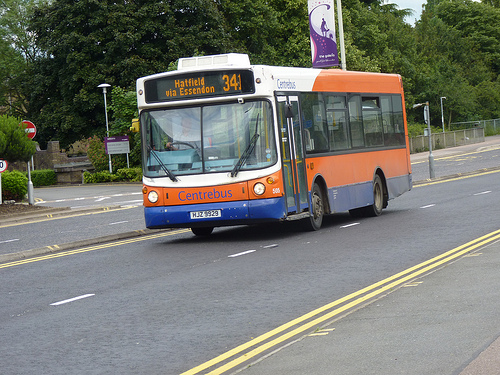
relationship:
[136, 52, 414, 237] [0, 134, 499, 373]
bus on road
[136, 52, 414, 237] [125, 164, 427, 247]
bus has a bottom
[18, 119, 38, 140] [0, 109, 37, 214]
sign behind tree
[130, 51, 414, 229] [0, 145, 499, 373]
bus driving on driveway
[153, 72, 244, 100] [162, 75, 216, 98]
marquee displaying destination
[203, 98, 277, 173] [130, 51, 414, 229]
front window built into bus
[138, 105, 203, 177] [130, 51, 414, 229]
front window built into bus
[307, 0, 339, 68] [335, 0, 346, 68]
banner hanging from pole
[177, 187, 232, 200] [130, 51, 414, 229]
name on bus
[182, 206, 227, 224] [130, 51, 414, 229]
license plate on bus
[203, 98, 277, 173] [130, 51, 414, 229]
front window in front of bus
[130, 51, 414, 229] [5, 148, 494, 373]
bus driving down street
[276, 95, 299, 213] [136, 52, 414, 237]
doors on bus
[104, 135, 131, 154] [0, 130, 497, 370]
sign on street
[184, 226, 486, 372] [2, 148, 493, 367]
curb dividing road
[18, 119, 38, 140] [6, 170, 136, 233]
sign in a driveway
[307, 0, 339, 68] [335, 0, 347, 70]
banner on pole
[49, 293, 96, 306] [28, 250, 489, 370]
median on road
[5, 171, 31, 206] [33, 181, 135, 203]
bush in driveway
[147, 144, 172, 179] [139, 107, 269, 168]
wiper on windshield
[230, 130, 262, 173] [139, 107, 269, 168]
wiper on windshield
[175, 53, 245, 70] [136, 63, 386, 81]
air conditioner on roof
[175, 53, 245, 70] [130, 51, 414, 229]
air conditioner on bus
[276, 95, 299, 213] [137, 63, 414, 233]
doors on bus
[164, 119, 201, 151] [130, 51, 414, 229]
driver of bus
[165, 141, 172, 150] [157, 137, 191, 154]
hand on wheel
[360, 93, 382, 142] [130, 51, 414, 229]
window on bus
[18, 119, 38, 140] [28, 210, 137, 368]
sign by road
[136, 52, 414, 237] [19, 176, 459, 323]
bus on road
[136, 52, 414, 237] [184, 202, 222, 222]
bus has license plate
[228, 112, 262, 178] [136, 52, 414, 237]
wiper on bus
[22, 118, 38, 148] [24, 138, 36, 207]
sign on pole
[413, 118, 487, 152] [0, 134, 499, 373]
fence by road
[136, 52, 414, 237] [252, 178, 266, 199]
bus has headlight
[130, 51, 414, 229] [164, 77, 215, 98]
bus has destination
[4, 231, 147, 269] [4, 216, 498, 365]
median on road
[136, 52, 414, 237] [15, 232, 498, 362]
bus on road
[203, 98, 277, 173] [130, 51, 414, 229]
front window on bus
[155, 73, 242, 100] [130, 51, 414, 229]
marquee on bus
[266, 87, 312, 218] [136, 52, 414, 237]
doors on bus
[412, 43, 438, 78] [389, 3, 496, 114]
leaves on tree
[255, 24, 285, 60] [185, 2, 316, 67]
leaves on tree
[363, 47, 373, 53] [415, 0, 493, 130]
leaves on tree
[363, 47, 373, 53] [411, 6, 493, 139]
leaves on tree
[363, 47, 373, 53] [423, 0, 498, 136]
leaves on tree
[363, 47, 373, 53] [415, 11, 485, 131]
leaves on tree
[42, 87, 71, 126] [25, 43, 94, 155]
leaves on tree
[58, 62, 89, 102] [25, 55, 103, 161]
leaves on tree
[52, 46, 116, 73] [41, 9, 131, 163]
leaves on tree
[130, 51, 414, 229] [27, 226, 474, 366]
bus driving down road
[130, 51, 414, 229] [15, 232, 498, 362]
bus on road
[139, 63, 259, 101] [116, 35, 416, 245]
destination on front of bus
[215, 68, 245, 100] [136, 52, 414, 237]
number on front of bus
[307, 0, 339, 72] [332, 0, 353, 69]
banner hanging from pole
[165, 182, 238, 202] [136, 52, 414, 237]
name on bus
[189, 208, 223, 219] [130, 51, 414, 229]
license plate on front of bus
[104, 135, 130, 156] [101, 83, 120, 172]
sign on poles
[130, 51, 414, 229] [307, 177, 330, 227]
bus has a front tire